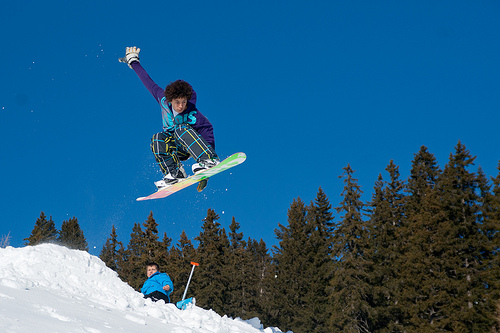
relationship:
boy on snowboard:
[118, 46, 218, 191] [136, 152, 247, 201]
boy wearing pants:
[118, 46, 218, 191] [150, 123, 216, 174]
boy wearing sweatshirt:
[118, 46, 218, 191] [130, 60, 213, 149]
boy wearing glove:
[118, 46, 218, 191] [117, 46, 140, 66]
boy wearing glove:
[118, 46, 218, 191] [196, 178, 208, 192]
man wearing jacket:
[141, 262, 175, 304] [140, 272, 173, 300]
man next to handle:
[141, 262, 175, 304] [177, 261, 200, 310]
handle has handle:
[177, 261, 200, 310] [180, 260, 199, 301]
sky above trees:
[1, 0, 500, 259] [23, 139, 500, 332]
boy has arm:
[118, 46, 218, 191] [118, 46, 164, 103]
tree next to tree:
[326, 161, 385, 332] [260, 197, 328, 332]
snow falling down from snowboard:
[201, 168, 231, 224] [136, 152, 247, 201]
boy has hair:
[118, 46, 218, 191] [164, 80, 195, 102]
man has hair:
[141, 262, 175, 304] [145, 261, 160, 270]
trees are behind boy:
[23, 139, 500, 332] [118, 46, 218, 191]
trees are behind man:
[23, 139, 500, 332] [141, 262, 175, 304]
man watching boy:
[141, 262, 175, 304] [118, 46, 218, 191]